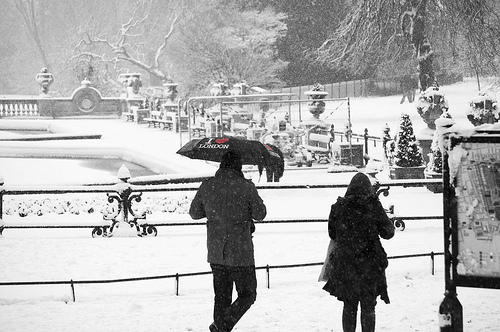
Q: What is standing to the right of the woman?
A: Sign.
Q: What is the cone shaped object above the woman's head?
A: Bush.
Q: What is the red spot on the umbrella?
A: Emblem.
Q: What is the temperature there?
A: Cold.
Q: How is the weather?
A: Snowy.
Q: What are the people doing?
A: Walking.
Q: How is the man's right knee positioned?
A: Bent.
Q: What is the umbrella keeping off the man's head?
A: Snow.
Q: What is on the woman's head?
A: Hood.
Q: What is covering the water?
A: Snow.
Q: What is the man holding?
A: An umbrella.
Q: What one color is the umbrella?
A: Black.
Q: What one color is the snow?
A: White.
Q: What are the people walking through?
A: Snow.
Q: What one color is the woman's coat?
A: Black.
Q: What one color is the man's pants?
A: Black.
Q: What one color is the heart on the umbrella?
A: Red.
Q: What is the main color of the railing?
A: Black.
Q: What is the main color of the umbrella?
A: Black.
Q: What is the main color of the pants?
A: Black.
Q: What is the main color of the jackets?
A: Black.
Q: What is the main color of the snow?
A: White.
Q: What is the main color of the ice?
A: White.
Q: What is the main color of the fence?
A: Black.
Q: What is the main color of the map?
A: Black.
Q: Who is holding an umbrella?
A: The man.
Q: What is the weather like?
A: Snowy.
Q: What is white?
A: The snow.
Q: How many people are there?
A: Two.